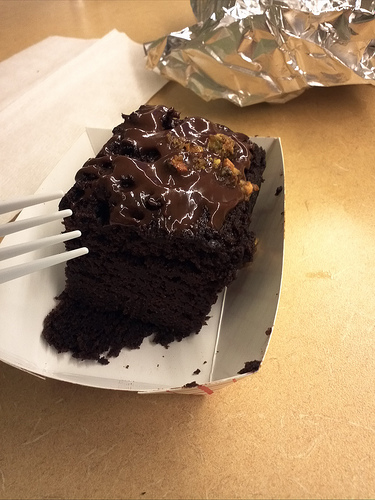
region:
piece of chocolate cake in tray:
[52, 91, 260, 354]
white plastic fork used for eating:
[0, 190, 94, 287]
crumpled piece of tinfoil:
[141, 2, 371, 103]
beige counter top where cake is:
[293, 220, 365, 490]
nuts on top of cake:
[172, 131, 255, 200]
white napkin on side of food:
[5, 32, 173, 114]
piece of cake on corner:
[235, 357, 263, 375]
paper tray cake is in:
[25, 357, 181, 430]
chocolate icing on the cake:
[171, 179, 226, 216]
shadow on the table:
[12, 395, 219, 490]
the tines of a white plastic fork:
[0, 188, 96, 286]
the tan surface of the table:
[45, 416, 365, 498]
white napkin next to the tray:
[5, 26, 142, 146]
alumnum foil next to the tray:
[138, 19, 373, 97]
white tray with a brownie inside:
[1, 108, 279, 394]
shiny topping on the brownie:
[85, 105, 239, 241]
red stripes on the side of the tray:
[184, 375, 252, 407]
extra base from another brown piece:
[36, 296, 175, 367]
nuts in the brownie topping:
[174, 127, 262, 203]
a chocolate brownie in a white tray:
[71, 126, 243, 337]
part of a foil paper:
[269, 32, 294, 55]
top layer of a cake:
[173, 152, 197, 184]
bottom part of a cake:
[124, 302, 177, 315]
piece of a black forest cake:
[133, 169, 215, 282]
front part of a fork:
[47, 256, 68, 266]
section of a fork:
[18, 208, 31, 270]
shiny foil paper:
[200, 50, 230, 75]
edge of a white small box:
[229, 293, 265, 350]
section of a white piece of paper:
[69, 53, 117, 109]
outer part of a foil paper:
[254, 39, 319, 82]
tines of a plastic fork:
[0, 181, 100, 319]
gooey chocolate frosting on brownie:
[102, 94, 258, 291]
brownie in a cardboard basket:
[58, 117, 299, 401]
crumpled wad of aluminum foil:
[141, 2, 372, 117]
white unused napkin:
[2, 21, 165, 197]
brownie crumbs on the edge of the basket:
[192, 351, 280, 428]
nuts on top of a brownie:
[160, 124, 263, 212]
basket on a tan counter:
[18, 363, 315, 481]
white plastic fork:
[0, 189, 95, 290]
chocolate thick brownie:
[79, 162, 214, 318]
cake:
[52, 88, 271, 367]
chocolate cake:
[52, 104, 268, 350]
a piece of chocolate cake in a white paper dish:
[1, 113, 290, 402]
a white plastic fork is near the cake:
[0, 92, 106, 398]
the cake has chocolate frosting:
[44, 91, 266, 363]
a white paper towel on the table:
[0, 22, 172, 225]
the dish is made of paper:
[14, 111, 294, 434]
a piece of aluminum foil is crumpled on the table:
[142, 4, 373, 106]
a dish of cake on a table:
[15, 110, 282, 400]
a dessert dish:
[13, 105, 292, 410]